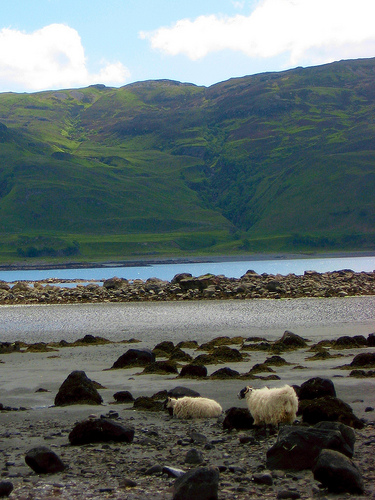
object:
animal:
[237, 381, 298, 429]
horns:
[243, 385, 246, 392]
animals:
[162, 392, 222, 422]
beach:
[0, 268, 374, 499]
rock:
[49, 368, 103, 406]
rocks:
[24, 442, 68, 472]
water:
[0, 255, 374, 291]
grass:
[0, 57, 374, 261]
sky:
[0, 0, 374, 95]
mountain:
[0, 56, 374, 267]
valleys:
[186, 120, 256, 230]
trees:
[24, 245, 39, 256]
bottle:
[154, 462, 192, 473]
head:
[235, 382, 249, 400]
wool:
[259, 394, 281, 417]